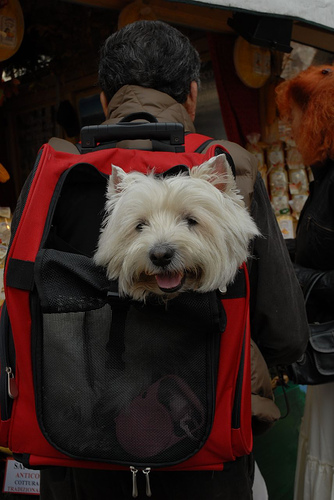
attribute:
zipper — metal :
[128, 466, 152, 497]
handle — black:
[78, 120, 185, 147]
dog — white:
[92, 161, 252, 284]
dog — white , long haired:
[92, 153, 257, 295]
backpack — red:
[2, 142, 253, 473]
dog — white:
[92, 153, 267, 303]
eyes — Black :
[133, 215, 198, 231]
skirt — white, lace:
[292, 385, 333, 499]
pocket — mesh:
[39, 298, 205, 462]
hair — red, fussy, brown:
[273, 64, 333, 163]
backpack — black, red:
[3, 122, 263, 478]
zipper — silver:
[124, 462, 153, 497]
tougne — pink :
[160, 275, 178, 285]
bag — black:
[288, 256, 332, 384]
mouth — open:
[143, 264, 195, 295]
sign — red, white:
[6, 439, 43, 499]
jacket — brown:
[90, 90, 207, 149]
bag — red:
[2, 110, 257, 498]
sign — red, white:
[1, 453, 43, 498]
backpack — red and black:
[31, 140, 262, 323]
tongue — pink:
[149, 269, 186, 289]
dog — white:
[112, 173, 201, 251]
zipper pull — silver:
[142, 466, 152, 498]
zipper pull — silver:
[128, 464, 139, 498]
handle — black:
[73, 117, 190, 148]